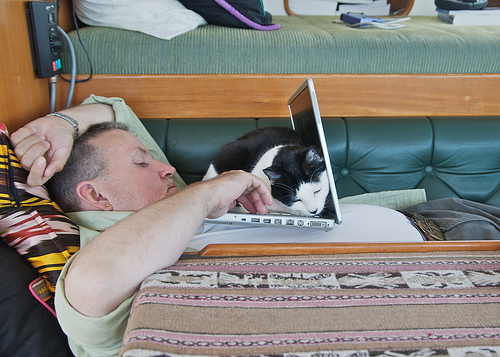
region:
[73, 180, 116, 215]
The man is wearing a earring.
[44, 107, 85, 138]
The man is wearing a watch.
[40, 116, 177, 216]
The man's hair is black and gray.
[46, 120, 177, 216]
The man has short hair.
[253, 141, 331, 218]
The cat's face is black and white.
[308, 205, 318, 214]
The cat's nose is small.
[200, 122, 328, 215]
The cat is laying on the laptop.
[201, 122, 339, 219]
The cat's fur is black and white.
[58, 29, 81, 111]
The wire is blue in color.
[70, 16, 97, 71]
The wire is black in color.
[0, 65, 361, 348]
A man on a couch with a cat on his laptop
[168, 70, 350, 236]
cat lying on a laptop computer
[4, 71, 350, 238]
this guy is actually trying to work around the cat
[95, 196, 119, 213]
dude is wearing an earring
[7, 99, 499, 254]
dude is lying on a sofa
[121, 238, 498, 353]
this thing in front of the guy is a table or something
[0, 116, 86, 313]
guy leaning against a striped pillow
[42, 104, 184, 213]
guy has a crew cut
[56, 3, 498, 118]
a bed above the sofa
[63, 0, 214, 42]
pillow with white pillowcase on the upper bed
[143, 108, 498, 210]
the sofa back is greenish leather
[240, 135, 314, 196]
A cat in the room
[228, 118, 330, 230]
Black and white cat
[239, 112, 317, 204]
A cat sitting on the laptop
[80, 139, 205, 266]
A man on the couch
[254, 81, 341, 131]
Screen of a laptop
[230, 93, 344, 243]
A laptop in the photo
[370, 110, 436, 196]
A couch in the photo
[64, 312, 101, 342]
A green shirt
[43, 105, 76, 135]
A bracelet on the hand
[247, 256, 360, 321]
A rug in the photo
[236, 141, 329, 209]
a cat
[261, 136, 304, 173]
the cat is black and white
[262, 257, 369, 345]
a rug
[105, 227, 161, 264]
the arm of the man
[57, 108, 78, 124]
man is wearing a watch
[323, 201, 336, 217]
whiskers on the cat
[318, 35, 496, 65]
a cushion is green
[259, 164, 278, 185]
right ear of the cat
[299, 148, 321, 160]
left ear of the cat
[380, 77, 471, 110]
the wood is brown